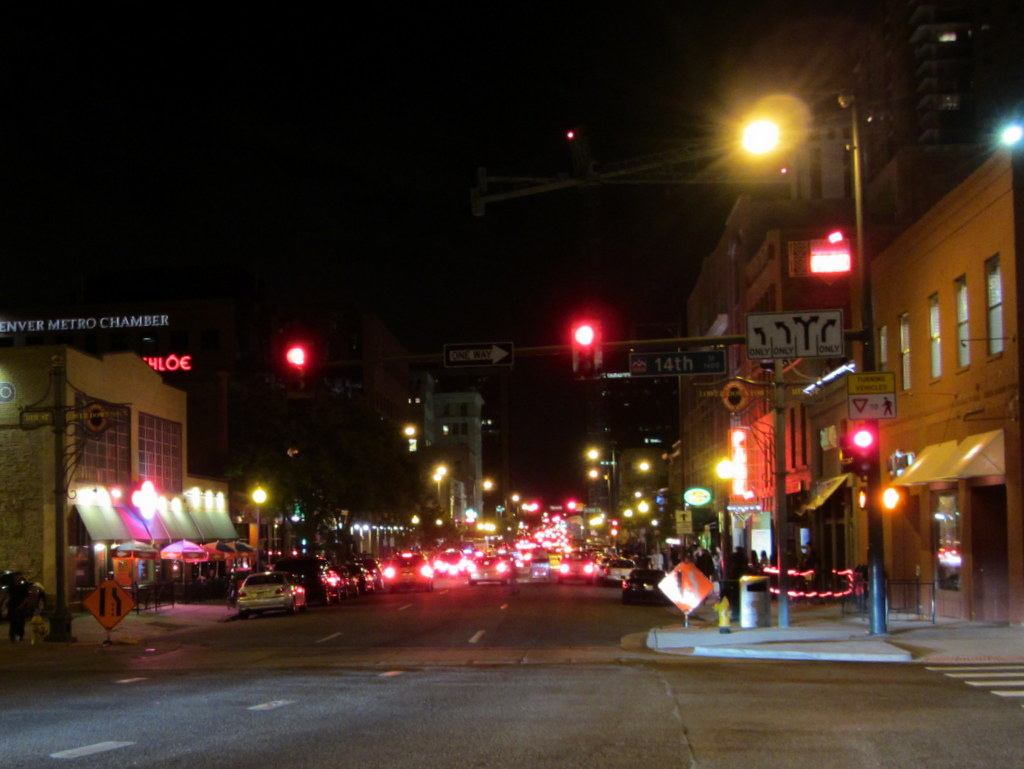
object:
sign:
[658, 559, 714, 628]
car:
[622, 569, 674, 607]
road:
[5, 552, 1024, 769]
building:
[667, 1, 1023, 625]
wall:
[870, 141, 1024, 628]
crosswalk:
[927, 661, 1023, 703]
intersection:
[0, 579, 1024, 769]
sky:
[0, 0, 1024, 520]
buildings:
[0, 0, 1021, 626]